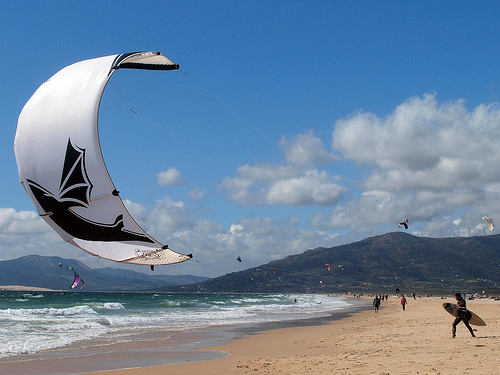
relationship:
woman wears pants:
[402, 294, 410, 309] [399, 301, 405, 306]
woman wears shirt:
[402, 294, 410, 309] [399, 298, 405, 300]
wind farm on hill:
[415, 227, 499, 239] [196, 226, 499, 291]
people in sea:
[339, 278, 495, 331] [7, 281, 350, 370]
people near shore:
[339, 278, 495, 331] [117, 287, 497, 374]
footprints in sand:
[265, 336, 469, 373] [117, 287, 497, 374]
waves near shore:
[7, 304, 143, 351] [117, 287, 497, 374]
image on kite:
[23, 143, 156, 250] [14, 52, 192, 270]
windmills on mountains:
[408, 221, 500, 238] [3, 230, 499, 297]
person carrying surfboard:
[443, 286, 483, 345] [440, 301, 487, 329]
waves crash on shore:
[7, 304, 143, 351] [117, 287, 497, 374]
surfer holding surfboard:
[443, 286, 483, 345] [440, 301, 487, 329]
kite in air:
[14, 52, 192, 270] [3, 0, 500, 250]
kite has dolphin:
[14, 52, 192, 270] [23, 143, 156, 250]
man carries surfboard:
[443, 286, 483, 345] [440, 301, 487, 329]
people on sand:
[339, 278, 495, 331] [117, 287, 497, 374]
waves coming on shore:
[7, 304, 143, 351] [117, 287, 497, 374]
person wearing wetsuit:
[443, 286, 483, 345] [453, 301, 473, 320]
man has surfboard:
[443, 286, 483, 345] [440, 301, 487, 329]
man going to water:
[443, 286, 483, 345] [7, 281, 350, 370]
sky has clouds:
[3, 0, 500, 250] [245, 94, 498, 233]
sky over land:
[3, 0, 500, 250] [4, 222, 497, 372]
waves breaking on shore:
[7, 304, 143, 351] [117, 287, 497, 374]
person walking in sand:
[443, 286, 483, 345] [117, 287, 497, 374]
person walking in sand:
[395, 292, 412, 310] [117, 287, 497, 374]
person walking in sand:
[369, 292, 383, 314] [117, 287, 497, 374]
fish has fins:
[23, 143, 156, 250] [49, 136, 95, 204]